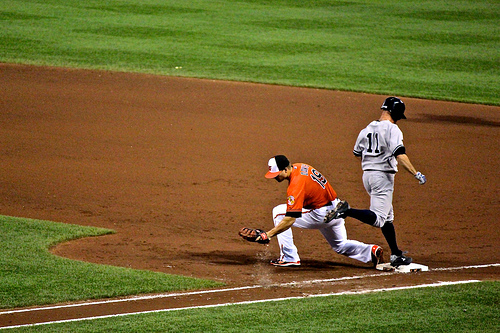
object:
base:
[376, 260, 431, 274]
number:
[366, 132, 379, 153]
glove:
[238, 226, 272, 246]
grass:
[0, 0, 500, 103]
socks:
[348, 208, 403, 256]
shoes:
[269, 257, 302, 268]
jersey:
[285, 163, 338, 218]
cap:
[264, 154, 290, 179]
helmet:
[380, 96, 408, 122]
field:
[0, 0, 500, 333]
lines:
[0, 261, 500, 333]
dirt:
[0, 59, 500, 333]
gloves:
[414, 170, 427, 186]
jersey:
[352, 119, 407, 174]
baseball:
[179, 65, 480, 274]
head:
[264, 155, 292, 184]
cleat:
[270, 258, 302, 267]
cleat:
[323, 200, 347, 224]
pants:
[272, 199, 374, 263]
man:
[239, 155, 395, 275]